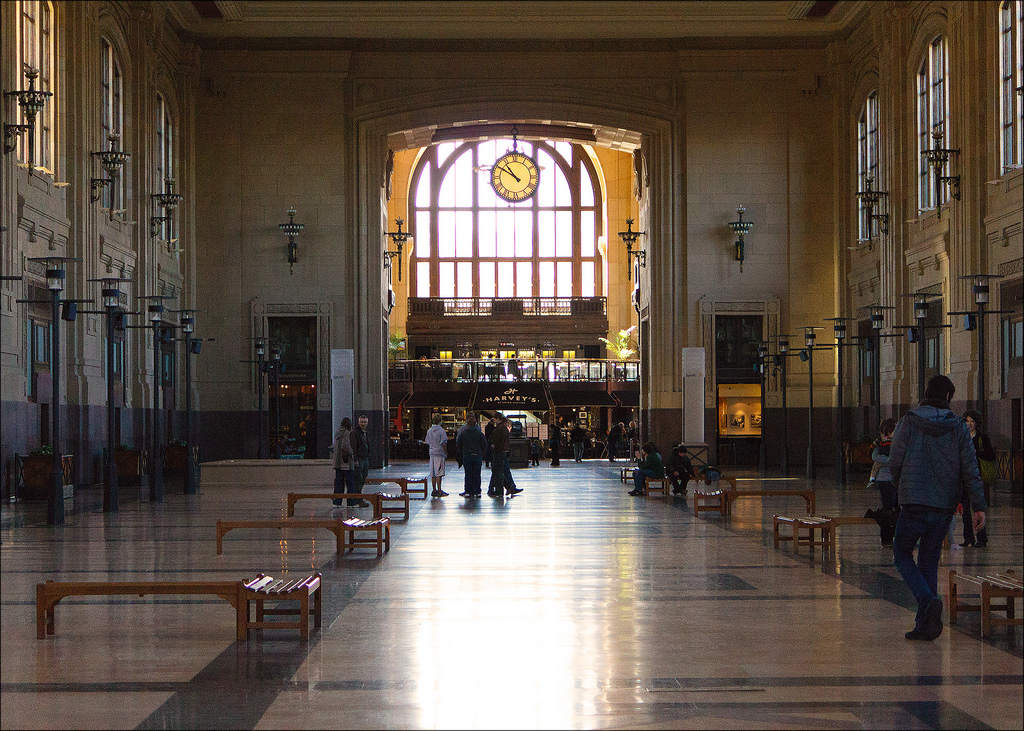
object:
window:
[479, 261, 533, 306]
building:
[0, 2, 1021, 731]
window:
[536, 141, 572, 208]